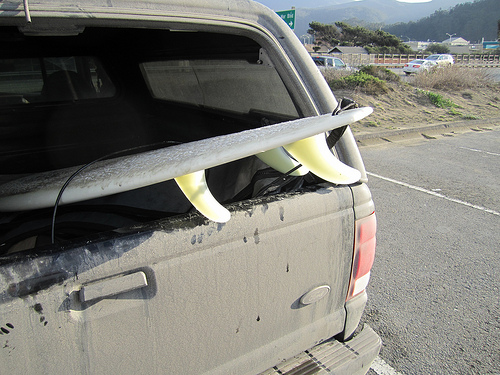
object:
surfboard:
[0, 106, 375, 224]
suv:
[1, 1, 384, 373]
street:
[306, 54, 499, 78]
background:
[259, 0, 499, 90]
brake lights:
[353, 209, 379, 275]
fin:
[283, 132, 364, 186]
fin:
[173, 171, 231, 223]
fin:
[255, 148, 311, 179]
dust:
[0, 0, 382, 374]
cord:
[48, 137, 183, 250]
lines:
[369, 171, 500, 214]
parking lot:
[2, 3, 499, 375]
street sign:
[273, 8, 297, 30]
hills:
[300, 0, 352, 45]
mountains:
[400, 1, 476, 30]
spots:
[252, 230, 262, 245]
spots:
[278, 204, 286, 222]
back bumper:
[240, 319, 383, 374]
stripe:
[451, 143, 499, 159]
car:
[312, 55, 351, 75]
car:
[402, 56, 438, 77]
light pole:
[448, 33, 453, 46]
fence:
[311, 50, 498, 68]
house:
[328, 44, 368, 55]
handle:
[79, 270, 149, 304]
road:
[354, 122, 499, 371]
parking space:
[356, 138, 499, 212]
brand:
[299, 283, 331, 305]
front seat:
[34, 69, 79, 103]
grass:
[346, 71, 379, 90]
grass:
[424, 91, 456, 109]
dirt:
[333, 88, 459, 135]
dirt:
[419, 80, 499, 116]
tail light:
[346, 208, 378, 301]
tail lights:
[403, 64, 409, 68]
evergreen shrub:
[307, 18, 344, 54]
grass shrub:
[412, 65, 431, 88]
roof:
[328, 42, 366, 54]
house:
[443, 35, 470, 46]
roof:
[440, 36, 470, 44]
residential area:
[302, 36, 499, 52]